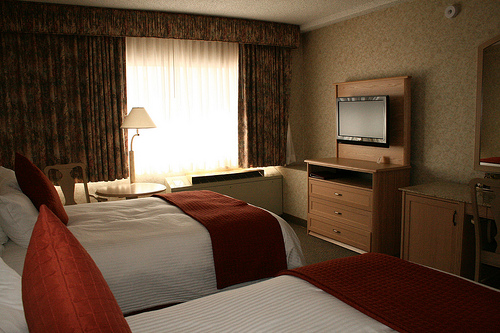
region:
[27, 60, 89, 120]
curtains hanging above the window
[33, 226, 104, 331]
a red pillow on the bed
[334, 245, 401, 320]
a blanket on the foot of the bed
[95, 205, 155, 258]
a white comforter on the bed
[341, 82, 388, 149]
a tv hanging on the wall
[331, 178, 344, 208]
a knob on a drawer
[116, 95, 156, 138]
a lamp shade on a light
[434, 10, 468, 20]
an alarm hanging on the wall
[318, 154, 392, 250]
a brown cabinet in the room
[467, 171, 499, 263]
a chair at a desk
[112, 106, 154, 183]
A lamp with a white lamp shade.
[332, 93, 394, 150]
A mounted television.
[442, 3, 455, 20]
A fire alarm on a wall.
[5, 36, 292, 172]
Curtains covering a window.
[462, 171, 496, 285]
A chair at a desk.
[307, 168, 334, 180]
A notebook on a shelf.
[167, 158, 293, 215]
A beige airconditioning unit.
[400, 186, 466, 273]
A door on a cabinet.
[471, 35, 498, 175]
A mirror hanging on a wall.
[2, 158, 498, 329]
Two beds in a hotel room.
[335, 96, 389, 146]
a small black t.v.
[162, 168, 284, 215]
a large ac unit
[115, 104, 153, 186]
a tall floor lamp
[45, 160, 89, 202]
part of a brown chair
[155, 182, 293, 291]
a long red blanket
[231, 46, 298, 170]
part of a curtain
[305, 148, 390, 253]
a brown t.v. cabinet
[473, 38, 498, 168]
part of a wall mirror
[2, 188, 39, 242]
a large white pillow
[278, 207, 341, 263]
part of a carpet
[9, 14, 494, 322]
Photo taken in a hotel room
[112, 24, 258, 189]
Sunlight out the window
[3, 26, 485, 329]
Photo taken during the day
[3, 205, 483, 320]
Two beds in the room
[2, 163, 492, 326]
The beds are made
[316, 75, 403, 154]
Flat screen tv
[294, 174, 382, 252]
Three drawers on the dresser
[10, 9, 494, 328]
Nobody in the photo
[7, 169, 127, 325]
Red and white pillows on the beds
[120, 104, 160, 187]
Lamp over the table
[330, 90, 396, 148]
wall mounted black television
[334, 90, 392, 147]
flat screen television on the wall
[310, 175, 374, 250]
three wooden dresser drawers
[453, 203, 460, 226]
black handle on a desk cabinet door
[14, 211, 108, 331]
red decorative pillow on a bed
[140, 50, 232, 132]
sheer white curtains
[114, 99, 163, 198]
tall lamp with a white lamp shade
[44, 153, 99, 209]
wooden chair back by a bed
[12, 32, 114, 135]
dark colored curtains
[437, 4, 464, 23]
white fire alarm on the wall